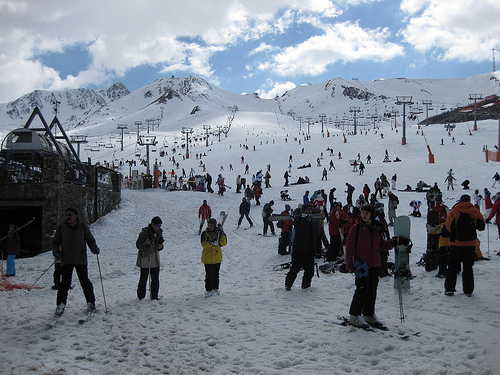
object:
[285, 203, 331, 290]
skier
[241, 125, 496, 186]
snow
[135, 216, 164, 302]
person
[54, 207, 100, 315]
person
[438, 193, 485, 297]
person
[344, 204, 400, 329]
person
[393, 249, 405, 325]
snow poles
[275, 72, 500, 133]
mountain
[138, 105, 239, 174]
poles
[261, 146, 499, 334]
peope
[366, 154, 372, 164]
skier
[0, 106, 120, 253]
train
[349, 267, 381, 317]
pants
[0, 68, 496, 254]
hill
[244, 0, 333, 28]
cloud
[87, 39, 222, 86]
cloud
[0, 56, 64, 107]
cloud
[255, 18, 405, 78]
cloud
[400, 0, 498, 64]
cloud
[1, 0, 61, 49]
cloud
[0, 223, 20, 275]
person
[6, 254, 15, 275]
pants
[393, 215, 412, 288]
skis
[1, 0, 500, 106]
sky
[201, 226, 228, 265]
yellow jacket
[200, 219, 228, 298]
person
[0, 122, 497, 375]
field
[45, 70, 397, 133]
snow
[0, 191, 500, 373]
snow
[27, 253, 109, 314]
ski poles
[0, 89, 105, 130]
mountain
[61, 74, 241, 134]
mountain